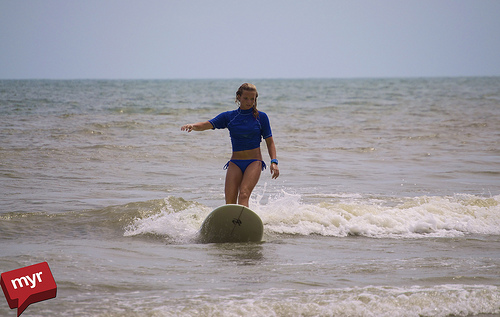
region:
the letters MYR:
[0, 267, 85, 309]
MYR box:
[5, 257, 88, 313]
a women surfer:
[176, 70, 326, 250]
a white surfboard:
[185, 203, 300, 268]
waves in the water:
[65, 177, 185, 273]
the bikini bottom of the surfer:
[221, 155, 279, 172]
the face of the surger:
[218, 80, 278, 116]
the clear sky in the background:
[97, 15, 283, 75]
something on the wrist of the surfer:
[267, 150, 292, 175]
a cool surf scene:
[33, 48, 418, 264]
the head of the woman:
[223, 80, 259, 115]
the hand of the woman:
[266, 158, 281, 180]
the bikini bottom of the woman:
[218, 152, 266, 172]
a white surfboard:
[193, 198, 267, 250]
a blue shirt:
[205, 106, 277, 152]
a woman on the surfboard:
[171, 81, 283, 211]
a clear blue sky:
[0, 0, 499, 80]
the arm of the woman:
[179, 105, 231, 137]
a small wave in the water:
[0, 187, 499, 245]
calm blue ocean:
[1, 74, 498, 107]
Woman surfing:
[196, 82, 274, 242]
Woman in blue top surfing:
[217, 73, 272, 220]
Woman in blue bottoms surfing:
[190, 87, 282, 233]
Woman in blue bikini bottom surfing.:
[160, 80, 327, 261]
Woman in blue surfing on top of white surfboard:
[142, 77, 300, 246]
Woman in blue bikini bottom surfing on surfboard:
[178, 82, 264, 269]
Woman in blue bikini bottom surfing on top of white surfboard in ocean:
[177, 81, 297, 251]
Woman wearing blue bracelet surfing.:
[152, 92, 299, 242]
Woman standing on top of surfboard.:
[181, 54, 321, 296]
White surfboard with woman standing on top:
[167, 61, 333, 261]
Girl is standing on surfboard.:
[181, 78, 283, 243]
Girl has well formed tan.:
[176, 82, 283, 204]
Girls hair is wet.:
[228, 81, 261, 126]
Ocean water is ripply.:
[0, 75, 499, 314]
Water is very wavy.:
[1, 72, 499, 314]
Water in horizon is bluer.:
[1, 74, 499, 315]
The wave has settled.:
[1, 177, 499, 251]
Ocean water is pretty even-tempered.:
[1, 73, 498, 315]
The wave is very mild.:
[1, 185, 499, 266]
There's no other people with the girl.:
[0, 67, 499, 315]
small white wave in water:
[340, 205, 405, 235]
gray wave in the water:
[13, 187, 120, 254]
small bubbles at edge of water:
[300, 288, 377, 314]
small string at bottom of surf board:
[215, 202, 266, 238]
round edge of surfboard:
[187, 191, 274, 261]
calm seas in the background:
[319, 65, 411, 126]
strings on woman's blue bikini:
[204, 142, 261, 173]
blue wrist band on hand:
[260, 149, 300, 181]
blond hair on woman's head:
[230, 78, 284, 105]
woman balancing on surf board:
[134, 74, 334, 269]